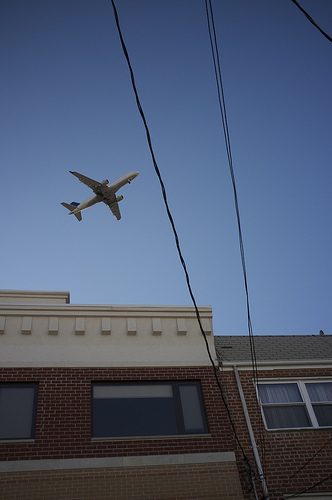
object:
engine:
[116, 195, 124, 202]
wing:
[103, 193, 122, 220]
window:
[91, 379, 208, 437]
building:
[214, 334, 332, 500]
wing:
[68, 170, 109, 196]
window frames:
[0, 381, 38, 442]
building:
[0, 288, 243, 499]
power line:
[112, 0, 248, 462]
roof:
[214, 330, 332, 363]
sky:
[0, 1, 332, 334]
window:
[304, 383, 332, 427]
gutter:
[221, 361, 332, 373]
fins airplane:
[60, 193, 102, 221]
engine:
[95, 179, 109, 190]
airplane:
[60, 171, 139, 222]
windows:
[304, 380, 332, 429]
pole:
[233, 365, 270, 499]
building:
[0, 288, 332, 500]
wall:
[1, 368, 268, 498]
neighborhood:
[0, 288, 332, 499]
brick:
[47, 411, 72, 434]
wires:
[110, 0, 332, 499]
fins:
[60, 202, 82, 222]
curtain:
[257, 382, 313, 428]